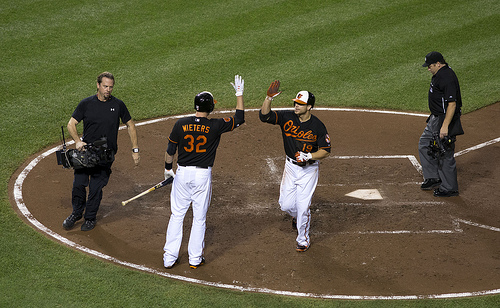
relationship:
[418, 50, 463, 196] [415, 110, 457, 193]
umpire on pants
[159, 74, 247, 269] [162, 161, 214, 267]
man wearing pants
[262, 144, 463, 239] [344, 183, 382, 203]
chalk line around home plate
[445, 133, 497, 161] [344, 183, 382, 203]
chalk line around home plate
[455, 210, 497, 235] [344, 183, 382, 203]
chalk line around home plate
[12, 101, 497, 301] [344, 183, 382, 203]
chalk line around home plate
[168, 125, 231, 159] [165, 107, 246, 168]
number on back of jerzee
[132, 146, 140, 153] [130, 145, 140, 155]
black watch on left wrist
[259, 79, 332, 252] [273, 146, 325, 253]
man wearing pants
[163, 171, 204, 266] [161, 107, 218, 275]
persons leg on person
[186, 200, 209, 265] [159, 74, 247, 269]
leg on man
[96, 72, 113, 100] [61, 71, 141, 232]
head of a person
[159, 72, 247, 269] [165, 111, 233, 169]
man wearing a jersey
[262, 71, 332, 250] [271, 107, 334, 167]
man wearing a jersey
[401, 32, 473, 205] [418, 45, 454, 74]
umpire wearing a hat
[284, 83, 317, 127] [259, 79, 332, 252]
head on man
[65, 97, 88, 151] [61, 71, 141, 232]
arm on person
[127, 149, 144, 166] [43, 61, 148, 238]
hand on person